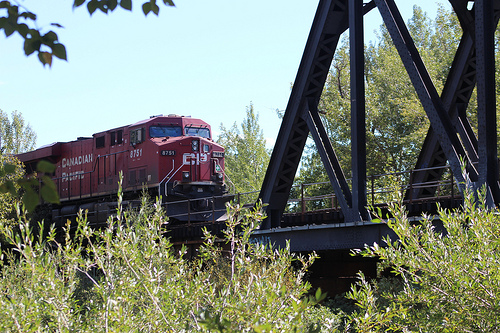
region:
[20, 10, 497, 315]
The train is approaching a bridge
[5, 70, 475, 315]
The train is going to the city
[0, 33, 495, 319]
The train is crossing a border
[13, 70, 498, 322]
The locomotive is pulling many cars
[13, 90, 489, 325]
The train has come from Canada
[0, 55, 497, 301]
The train is bringing consumer goods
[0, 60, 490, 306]
The train belongs to the railroad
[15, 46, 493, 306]
The train is traveling very fast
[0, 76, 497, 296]
The train is running in daytime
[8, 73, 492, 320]
The train is out in the sunshine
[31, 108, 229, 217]
red train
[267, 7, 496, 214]
bridge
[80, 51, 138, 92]
white clouds in blue sky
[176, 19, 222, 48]
white clouds in blue sky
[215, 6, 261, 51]
white clouds in blue sky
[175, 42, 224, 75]
white clouds in blue sky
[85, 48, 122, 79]
white clouds in blue sky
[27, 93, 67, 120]
white clouds in blue sky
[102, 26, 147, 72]
white clouds in blue sky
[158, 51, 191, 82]
white clouds in blue sky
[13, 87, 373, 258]
A train is on the bridge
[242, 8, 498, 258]
The bridge is made of steel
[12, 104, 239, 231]
The red train is Canadian Pacific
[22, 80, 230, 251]
The train is painted red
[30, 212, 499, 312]
Trees are along the railway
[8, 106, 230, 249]
The train is made of metal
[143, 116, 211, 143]
The train has two front windows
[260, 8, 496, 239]
Metal crossbeams support the bridge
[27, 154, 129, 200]
A black railing is on the side of the train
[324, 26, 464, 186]
Trees are in the distance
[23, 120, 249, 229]
red train engine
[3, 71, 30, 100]
white clouds in blue sky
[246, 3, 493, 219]
brown bridge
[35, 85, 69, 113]
white clouds in blue sky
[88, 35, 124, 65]
white clouds in blue sky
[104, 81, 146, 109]
white clouds in blue sky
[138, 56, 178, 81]
white clouds in blue sky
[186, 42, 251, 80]
white clouds in blue sky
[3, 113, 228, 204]
Red train heading under bridge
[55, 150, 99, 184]
CANADIAN PACIFIC on red train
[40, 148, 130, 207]
Black railing on red train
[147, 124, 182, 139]
Window on red train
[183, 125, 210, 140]
Window on red train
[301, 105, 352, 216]
Steel beam supporting bridge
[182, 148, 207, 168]
White CP on red train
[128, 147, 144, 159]
White numbers on red train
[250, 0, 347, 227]
Steel beam on bridge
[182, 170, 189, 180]
Round headlight on red train